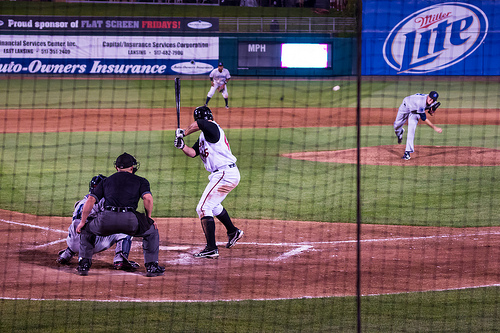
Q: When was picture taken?
A: At night.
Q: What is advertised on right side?
A: Miller lite beer.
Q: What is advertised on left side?
A: An insurance company.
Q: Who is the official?
A: The umpire.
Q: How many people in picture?
A: Five.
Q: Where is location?
A: A baseball stadium.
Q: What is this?
A: A baseball game.